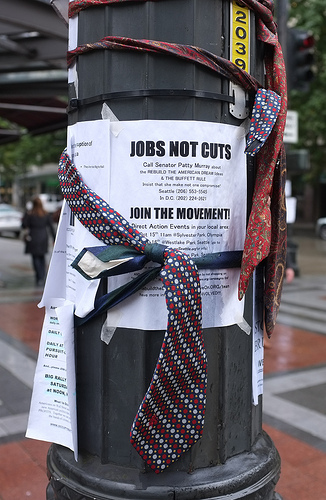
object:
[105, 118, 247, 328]
notice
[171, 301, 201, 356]
dots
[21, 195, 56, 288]
woman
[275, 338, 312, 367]
floor tiles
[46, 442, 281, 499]
base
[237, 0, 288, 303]
tie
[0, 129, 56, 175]
plants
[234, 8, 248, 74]
numbers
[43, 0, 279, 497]
pole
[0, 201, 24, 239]
car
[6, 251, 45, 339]
road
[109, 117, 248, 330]
paper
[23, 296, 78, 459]
paper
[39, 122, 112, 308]
paper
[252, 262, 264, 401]
paper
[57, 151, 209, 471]
tie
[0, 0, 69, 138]
building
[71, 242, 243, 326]
cloth